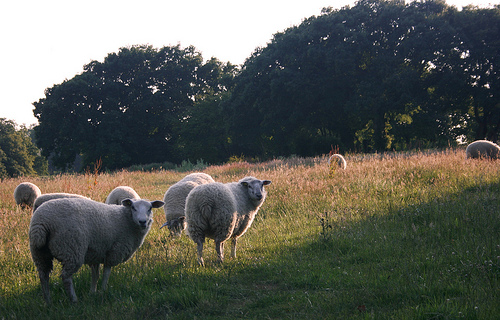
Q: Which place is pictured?
A: It is a field.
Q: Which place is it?
A: It is a field.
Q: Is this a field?
A: Yes, it is a field.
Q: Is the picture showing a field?
A: Yes, it is showing a field.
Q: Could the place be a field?
A: Yes, it is a field.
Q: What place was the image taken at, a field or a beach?
A: It was taken at a field.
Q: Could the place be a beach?
A: No, it is a field.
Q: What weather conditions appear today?
A: It is clear.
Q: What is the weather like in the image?
A: It is clear.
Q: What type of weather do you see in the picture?
A: It is clear.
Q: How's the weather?
A: It is clear.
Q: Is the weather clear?
A: Yes, it is clear.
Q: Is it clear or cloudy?
A: It is clear.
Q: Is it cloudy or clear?
A: It is clear.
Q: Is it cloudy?
A: No, it is clear.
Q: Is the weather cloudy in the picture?
A: No, it is clear.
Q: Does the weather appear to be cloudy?
A: No, it is clear.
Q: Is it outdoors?
A: Yes, it is outdoors.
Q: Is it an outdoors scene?
A: Yes, it is outdoors.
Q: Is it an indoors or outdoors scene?
A: It is outdoors.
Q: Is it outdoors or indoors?
A: It is outdoors.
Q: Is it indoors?
A: No, it is outdoors.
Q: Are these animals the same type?
A: Yes, all the animals are sheep.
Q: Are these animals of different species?
A: No, all the animals are sheep.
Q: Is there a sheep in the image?
A: Yes, there is a sheep.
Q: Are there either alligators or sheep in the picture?
A: Yes, there is a sheep.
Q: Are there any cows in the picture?
A: No, there are no cows.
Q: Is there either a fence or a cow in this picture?
A: No, there are no cows or fences.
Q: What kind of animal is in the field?
A: The animal is a sheep.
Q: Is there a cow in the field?
A: No, there is a sheep in the field.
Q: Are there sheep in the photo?
A: Yes, there is a sheep.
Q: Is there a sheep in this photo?
A: Yes, there is a sheep.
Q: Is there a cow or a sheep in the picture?
A: Yes, there is a sheep.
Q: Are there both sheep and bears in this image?
A: No, there is a sheep but no bears.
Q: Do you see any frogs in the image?
A: No, there are no frogs.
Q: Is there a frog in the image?
A: No, there are no frogs.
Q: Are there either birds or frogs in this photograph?
A: No, there are no frogs or birds.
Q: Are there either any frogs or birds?
A: No, there are no frogs or birds.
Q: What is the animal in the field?
A: The animal is a sheep.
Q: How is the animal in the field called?
A: The animal is a sheep.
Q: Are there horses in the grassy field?
A: No, there is a sheep in the field.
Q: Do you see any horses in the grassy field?
A: No, there is a sheep in the field.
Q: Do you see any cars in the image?
A: No, there are no cars.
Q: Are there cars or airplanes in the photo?
A: No, there are no cars or airplanes.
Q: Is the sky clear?
A: Yes, the sky is clear.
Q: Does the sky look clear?
A: Yes, the sky is clear.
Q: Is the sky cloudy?
A: No, the sky is clear.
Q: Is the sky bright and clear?
A: Yes, the sky is bright and clear.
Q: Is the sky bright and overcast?
A: No, the sky is bright but clear.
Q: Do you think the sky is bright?
A: Yes, the sky is bright.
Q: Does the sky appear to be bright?
A: Yes, the sky is bright.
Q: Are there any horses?
A: No, there are no horses.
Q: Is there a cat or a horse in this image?
A: No, there are no horses or cats.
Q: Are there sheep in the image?
A: Yes, there is a sheep.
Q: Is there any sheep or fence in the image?
A: Yes, there is a sheep.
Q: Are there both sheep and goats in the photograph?
A: No, there is a sheep but no goats.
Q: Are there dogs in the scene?
A: No, there are no dogs.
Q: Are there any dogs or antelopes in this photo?
A: No, there are no dogs or antelopes.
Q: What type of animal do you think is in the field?
A: The animal is a sheep.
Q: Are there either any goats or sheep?
A: Yes, there is a sheep.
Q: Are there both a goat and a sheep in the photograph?
A: No, there is a sheep but no goats.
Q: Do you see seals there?
A: No, there are no seals.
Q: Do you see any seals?
A: No, there are no seals.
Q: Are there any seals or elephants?
A: No, there are no seals or elephants.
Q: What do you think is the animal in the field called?
A: The animal is a sheep.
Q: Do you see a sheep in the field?
A: Yes, there is a sheep in the field.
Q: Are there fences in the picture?
A: No, there are no fences.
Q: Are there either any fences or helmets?
A: No, there are no fences or helmets.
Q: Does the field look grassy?
A: Yes, the field is grassy.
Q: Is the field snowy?
A: No, the field is grassy.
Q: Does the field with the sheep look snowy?
A: No, the field is grassy.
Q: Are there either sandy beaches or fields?
A: No, there is a field but it is grassy.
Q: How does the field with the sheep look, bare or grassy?
A: The field is grassy.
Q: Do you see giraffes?
A: No, there are no giraffes.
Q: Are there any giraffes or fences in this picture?
A: No, there are no giraffes or fences.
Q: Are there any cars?
A: No, there are no cars.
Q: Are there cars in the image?
A: No, there are no cars.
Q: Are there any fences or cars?
A: No, there are no cars or fences.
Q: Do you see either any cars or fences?
A: No, there are no cars or fences.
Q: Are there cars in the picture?
A: No, there are no cars.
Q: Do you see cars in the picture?
A: No, there are no cars.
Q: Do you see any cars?
A: No, there are no cars.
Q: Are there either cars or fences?
A: No, there are no cars or fences.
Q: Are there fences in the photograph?
A: No, there are no fences.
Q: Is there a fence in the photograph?
A: No, there are no fences.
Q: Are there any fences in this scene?
A: No, there are no fences.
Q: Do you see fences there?
A: No, there are no fences.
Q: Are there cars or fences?
A: No, there are no fences or cars.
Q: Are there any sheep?
A: Yes, there is a sheep.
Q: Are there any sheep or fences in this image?
A: Yes, there is a sheep.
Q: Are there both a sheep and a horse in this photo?
A: No, there is a sheep but no horses.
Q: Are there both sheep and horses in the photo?
A: No, there is a sheep but no horses.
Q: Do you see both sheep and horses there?
A: No, there is a sheep but no horses.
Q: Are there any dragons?
A: No, there are no dragons.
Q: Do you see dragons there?
A: No, there are no dragons.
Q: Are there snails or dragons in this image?
A: No, there are no dragons or snails.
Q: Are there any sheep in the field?
A: Yes, there is a sheep in the field.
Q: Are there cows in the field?
A: No, there is a sheep in the field.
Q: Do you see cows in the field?
A: No, there is a sheep in the field.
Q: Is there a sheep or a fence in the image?
A: Yes, there is a sheep.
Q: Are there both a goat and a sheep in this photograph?
A: No, there is a sheep but no goats.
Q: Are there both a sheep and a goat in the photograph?
A: No, there is a sheep but no goats.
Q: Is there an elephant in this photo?
A: No, there are no elephants.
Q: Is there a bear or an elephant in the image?
A: No, there are no elephants or bears.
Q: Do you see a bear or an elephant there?
A: No, there are no elephants or bears.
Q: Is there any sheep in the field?
A: Yes, there is a sheep in the field.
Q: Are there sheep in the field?
A: Yes, there is a sheep in the field.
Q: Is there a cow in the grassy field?
A: No, there is a sheep in the field.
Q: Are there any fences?
A: No, there are no fences.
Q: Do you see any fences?
A: No, there are no fences.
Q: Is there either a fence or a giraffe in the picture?
A: No, there are no fences or giraffes.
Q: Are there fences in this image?
A: No, there are no fences.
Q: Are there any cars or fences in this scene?
A: No, there are no fences or cars.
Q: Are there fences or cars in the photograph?
A: No, there are no fences or cars.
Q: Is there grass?
A: Yes, there is grass.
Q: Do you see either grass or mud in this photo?
A: Yes, there is grass.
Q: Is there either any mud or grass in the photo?
A: Yes, there is grass.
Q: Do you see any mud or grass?
A: Yes, there is grass.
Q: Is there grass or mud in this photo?
A: Yes, there is grass.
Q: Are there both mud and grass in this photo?
A: No, there is grass but no mud.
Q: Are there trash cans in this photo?
A: No, there are no trash cans.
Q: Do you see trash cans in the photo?
A: No, there are no trash cans.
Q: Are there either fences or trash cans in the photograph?
A: No, there are no trash cans or fences.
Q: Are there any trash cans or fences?
A: No, there are no trash cans or fences.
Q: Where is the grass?
A: The grass is in the field.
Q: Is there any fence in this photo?
A: No, there are no fences.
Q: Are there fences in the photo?
A: No, there are no fences.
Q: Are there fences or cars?
A: No, there are no fences or cars.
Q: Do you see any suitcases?
A: No, there are no suitcases.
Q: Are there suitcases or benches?
A: No, there are no suitcases or benches.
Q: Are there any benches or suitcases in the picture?
A: No, there are no suitcases or benches.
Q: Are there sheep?
A: Yes, there is a sheep.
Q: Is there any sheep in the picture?
A: Yes, there is a sheep.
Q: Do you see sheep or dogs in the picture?
A: Yes, there is a sheep.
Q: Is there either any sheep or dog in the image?
A: Yes, there is a sheep.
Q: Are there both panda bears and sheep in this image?
A: No, there is a sheep but no panda bears.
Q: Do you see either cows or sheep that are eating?
A: Yes, the sheep is eating.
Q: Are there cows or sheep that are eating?
A: Yes, the sheep is eating.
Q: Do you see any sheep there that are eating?
A: Yes, there is a sheep that is eating.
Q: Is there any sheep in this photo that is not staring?
A: Yes, there is a sheep that is eating.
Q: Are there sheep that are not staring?
A: Yes, there is a sheep that is eating.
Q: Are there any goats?
A: No, there are no goats.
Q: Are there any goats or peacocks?
A: No, there are no goats or peacocks.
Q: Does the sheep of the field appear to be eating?
A: Yes, the sheep is eating.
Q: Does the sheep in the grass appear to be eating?
A: Yes, the sheep is eating.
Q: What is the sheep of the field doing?
A: The sheep is eating.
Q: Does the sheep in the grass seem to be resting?
A: No, the sheep is eating.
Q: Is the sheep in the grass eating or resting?
A: The sheep is eating.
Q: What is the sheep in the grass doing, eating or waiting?
A: The sheep is eating.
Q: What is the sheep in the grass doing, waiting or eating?
A: The sheep is eating.